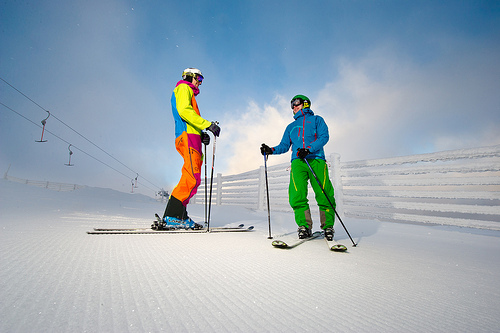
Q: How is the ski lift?
A: Empty.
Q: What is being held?
A: Poles.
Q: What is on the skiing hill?
A: Tow ropes.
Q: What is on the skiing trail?
A: The snow covered fence.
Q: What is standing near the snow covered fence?
A: 2 people.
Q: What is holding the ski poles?
A: The man.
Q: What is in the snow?
A: The lines.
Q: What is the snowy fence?
A: White.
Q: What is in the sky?
A: Clouds.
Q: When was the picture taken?
A: Day time.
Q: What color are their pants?
A: Green and orange.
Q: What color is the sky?
A: Blue and white.